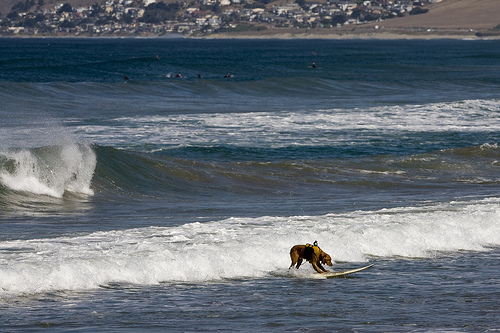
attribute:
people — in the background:
[120, 35, 295, 108]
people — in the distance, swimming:
[115, 64, 241, 85]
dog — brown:
[268, 233, 350, 276]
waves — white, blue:
[1, 138, 146, 203]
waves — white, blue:
[9, 33, 499, 325]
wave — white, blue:
[6, 138, 497, 184]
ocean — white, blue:
[4, 38, 498, 321]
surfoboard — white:
[270, 260, 377, 281]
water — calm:
[0, 37, 495, 332]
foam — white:
[0, 196, 499, 311]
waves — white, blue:
[146, 186, 228, 296]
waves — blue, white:
[355, 231, 421, 281]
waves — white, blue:
[2, 34, 497, 181]